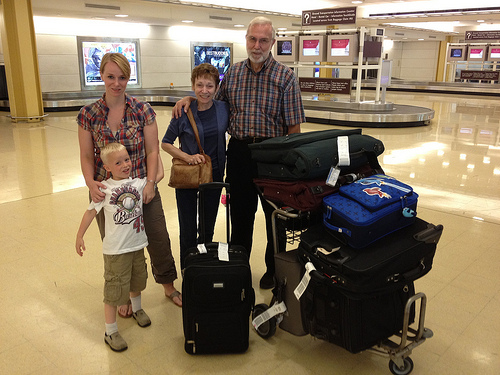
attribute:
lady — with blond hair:
[161, 61, 236, 301]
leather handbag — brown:
[159, 92, 225, 201]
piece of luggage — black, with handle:
[173, 234, 271, 369]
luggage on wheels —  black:
[248, 295, 450, 371]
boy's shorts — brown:
[90, 243, 157, 312]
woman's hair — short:
[181, 59, 232, 116]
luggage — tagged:
[172, 220, 269, 371]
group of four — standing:
[65, 10, 303, 373]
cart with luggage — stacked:
[248, 128, 442, 369]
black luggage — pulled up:
[176, 183, 286, 372]